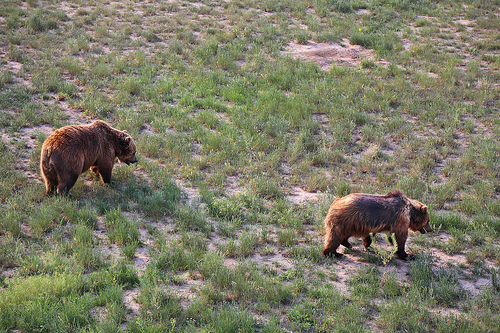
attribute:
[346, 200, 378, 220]
fur — brown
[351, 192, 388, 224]
fur — brown